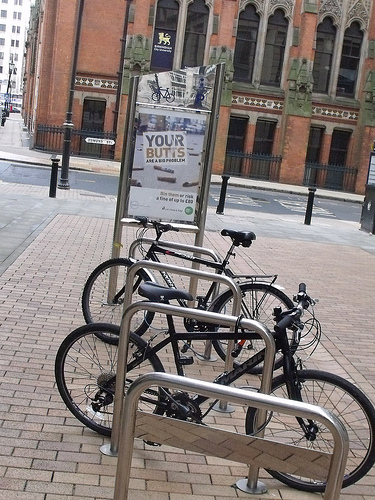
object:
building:
[22, 0, 375, 202]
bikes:
[54, 282, 373, 499]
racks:
[111, 371, 352, 500]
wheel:
[55, 317, 177, 441]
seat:
[136, 278, 196, 301]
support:
[101, 60, 228, 304]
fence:
[31, 121, 359, 193]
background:
[0, 0, 375, 214]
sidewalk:
[0, 181, 375, 491]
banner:
[151, 20, 181, 68]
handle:
[272, 311, 302, 335]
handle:
[295, 275, 310, 300]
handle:
[125, 207, 153, 226]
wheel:
[245, 364, 372, 498]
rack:
[111, 298, 277, 431]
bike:
[80, 218, 318, 375]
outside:
[0, 0, 374, 495]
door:
[74, 90, 110, 156]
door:
[221, 108, 253, 177]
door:
[298, 114, 324, 190]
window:
[335, 17, 367, 105]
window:
[308, 10, 338, 100]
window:
[258, 6, 295, 91]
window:
[228, 2, 264, 87]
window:
[177, 4, 217, 67]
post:
[49, 151, 61, 195]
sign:
[118, 60, 223, 227]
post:
[303, 183, 316, 225]